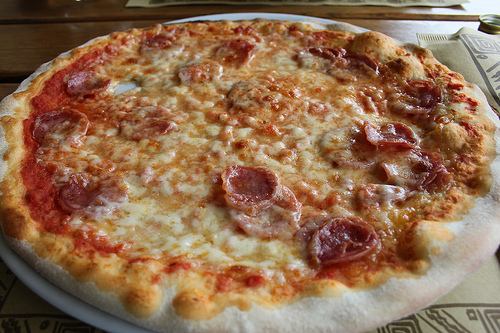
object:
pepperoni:
[220, 165, 283, 216]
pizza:
[1, 18, 499, 332]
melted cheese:
[54, 50, 429, 284]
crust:
[0, 17, 499, 332]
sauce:
[21, 50, 124, 260]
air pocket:
[396, 218, 463, 260]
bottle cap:
[476, 14, 499, 37]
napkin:
[413, 28, 499, 116]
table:
[0, 0, 499, 99]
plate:
[0, 12, 370, 333]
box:
[368, 248, 499, 333]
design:
[367, 302, 499, 333]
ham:
[53, 170, 127, 214]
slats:
[0, 19, 499, 79]